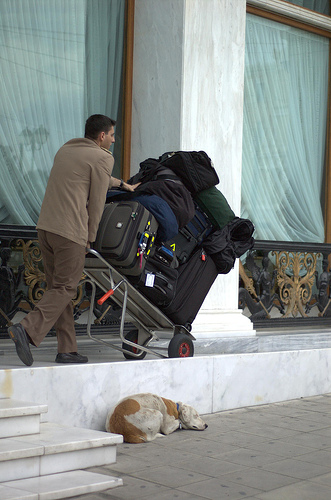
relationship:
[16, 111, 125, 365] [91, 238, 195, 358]
man pushing cart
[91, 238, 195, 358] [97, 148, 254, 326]
cart filled with luggage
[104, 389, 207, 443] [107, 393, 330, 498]
dog on walkway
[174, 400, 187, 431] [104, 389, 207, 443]
collar on dog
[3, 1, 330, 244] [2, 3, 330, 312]
curtain covering window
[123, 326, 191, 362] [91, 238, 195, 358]
wheels on cart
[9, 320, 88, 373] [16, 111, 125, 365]
shoes on man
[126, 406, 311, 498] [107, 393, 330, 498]
stains on walkway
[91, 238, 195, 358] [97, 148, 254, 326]
cart of luggage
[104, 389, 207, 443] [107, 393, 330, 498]
dog sleeping on walkway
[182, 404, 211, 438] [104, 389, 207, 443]
head of dog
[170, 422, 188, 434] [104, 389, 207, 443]
paw of dog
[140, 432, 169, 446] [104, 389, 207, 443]
tail of dog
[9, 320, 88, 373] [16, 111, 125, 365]
shoes of man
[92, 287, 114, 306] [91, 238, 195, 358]
handle on cart